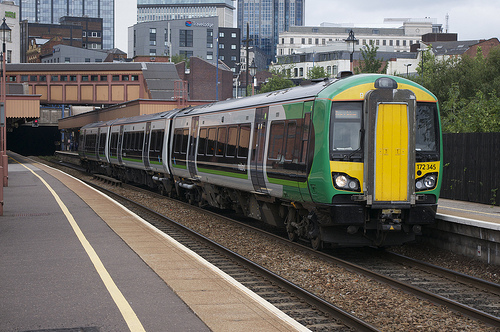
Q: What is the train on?
A: Tracks.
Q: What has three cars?
A: Train.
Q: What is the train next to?
A: Platform.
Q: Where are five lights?
A: Train.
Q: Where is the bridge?
A: Behind the train.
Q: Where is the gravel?
A: Between the tracks.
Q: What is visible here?
A: The train.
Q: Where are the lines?
A: On the platform.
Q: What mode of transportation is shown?
A: Train.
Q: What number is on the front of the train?
A: 172 345.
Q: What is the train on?
A: Tracks.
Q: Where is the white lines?
A: Outside of the tracks.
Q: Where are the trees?
A: Right side of the train.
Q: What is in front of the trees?
A: Fence.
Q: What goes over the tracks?
A: Bridge.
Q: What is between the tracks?
A: Gravel.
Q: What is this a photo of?
A: Train.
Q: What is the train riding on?
A: Tracks.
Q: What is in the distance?
A: Buildings.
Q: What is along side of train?
A: WIndows.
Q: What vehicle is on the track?
A: Green and yellow train.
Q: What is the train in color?
A: Green and yellow.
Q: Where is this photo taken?
A: Train station.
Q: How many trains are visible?
A: One.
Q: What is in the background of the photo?
A: Buildings.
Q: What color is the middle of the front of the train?
A: Yellow.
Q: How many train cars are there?
A: Three.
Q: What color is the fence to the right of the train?
A: Black.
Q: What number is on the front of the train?
A: 172-345.